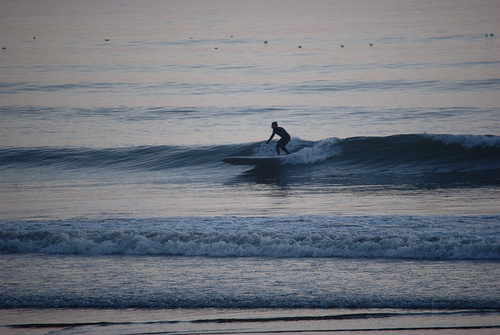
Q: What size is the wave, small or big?
A: Small.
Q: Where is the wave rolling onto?
A: Shore.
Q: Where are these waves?
A: Ocean.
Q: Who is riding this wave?
A: Surfer.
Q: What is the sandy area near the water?
A: Beach.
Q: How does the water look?
A: Calm.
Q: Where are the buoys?
A: Floating in the water.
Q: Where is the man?
A: On the surfboard.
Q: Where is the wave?
A: Beneath the surfboard.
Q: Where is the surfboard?
A: On the wave.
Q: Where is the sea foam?
A: On the waves.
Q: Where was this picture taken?
A: The ocean.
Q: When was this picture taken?
A: Evening.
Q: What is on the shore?
A: Sand.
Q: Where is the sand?
A: On the shore.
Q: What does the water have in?
A: Waves.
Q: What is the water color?
A: Blue.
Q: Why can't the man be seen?
A: Due to backlighting.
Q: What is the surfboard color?
A: White.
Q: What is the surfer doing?
A: Standing on surfboard.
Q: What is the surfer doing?
A: Riding a wave.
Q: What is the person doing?
A: Surfing.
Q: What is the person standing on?
A: Surfboard.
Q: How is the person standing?
A: With bent knees.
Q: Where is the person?
A: Ocean.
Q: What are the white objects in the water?
A: Waves.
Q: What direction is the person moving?
A: Left.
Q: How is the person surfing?
A: Alone.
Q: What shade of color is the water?
A: Blue.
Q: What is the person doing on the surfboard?
A: Riding a wave.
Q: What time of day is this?
A: Daylight hours.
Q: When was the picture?
A: Evening.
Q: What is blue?
A: Water.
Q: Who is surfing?
A: Man.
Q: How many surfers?
A: One.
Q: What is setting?
A: Sun.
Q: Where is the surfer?
A: Ocean.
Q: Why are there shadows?
A: Sunset.